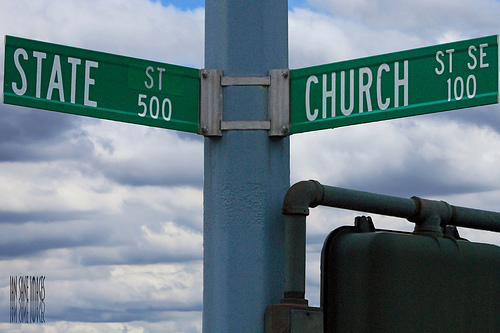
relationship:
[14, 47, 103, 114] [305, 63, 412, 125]
words have letters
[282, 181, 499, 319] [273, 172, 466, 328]
poles have a pipe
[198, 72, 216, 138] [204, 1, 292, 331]
bolts of pole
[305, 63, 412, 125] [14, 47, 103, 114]
letters have words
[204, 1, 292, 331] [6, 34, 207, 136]
pole has sign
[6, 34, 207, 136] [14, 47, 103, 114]
sign has words